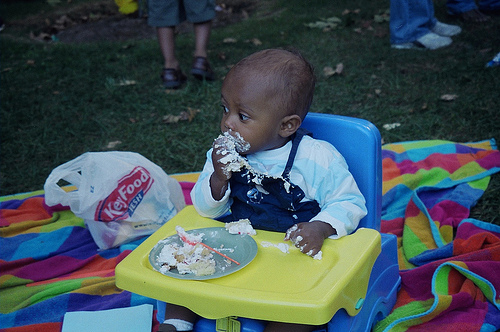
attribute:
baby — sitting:
[190, 45, 369, 257]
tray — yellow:
[114, 204, 381, 327]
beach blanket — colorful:
[1, 135, 499, 327]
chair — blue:
[156, 113, 400, 331]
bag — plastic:
[44, 150, 189, 249]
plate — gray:
[148, 225, 259, 281]